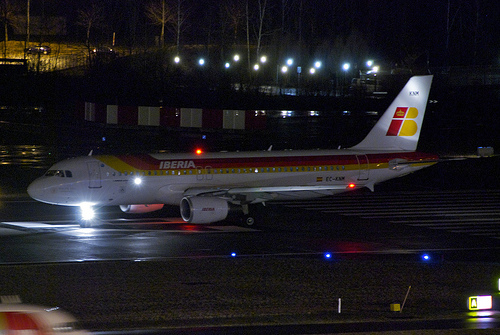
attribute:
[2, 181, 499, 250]
runway — black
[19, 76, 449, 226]
plane — white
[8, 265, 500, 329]
field — tan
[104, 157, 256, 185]
sign — yellow